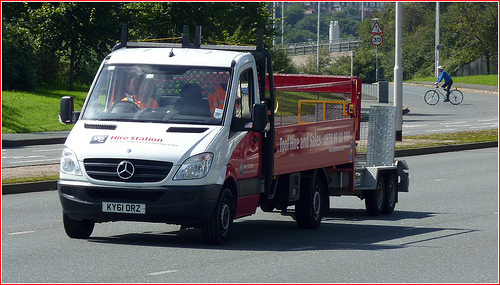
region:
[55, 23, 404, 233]
a truck riding down the street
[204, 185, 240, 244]
a tire on a truck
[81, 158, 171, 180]
a grate on the front of a train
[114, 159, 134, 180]
a silver Mercedes emblem on a truck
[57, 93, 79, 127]
a side mirror on a truck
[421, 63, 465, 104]
a person riding a bike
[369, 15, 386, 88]
a sign on the side of the road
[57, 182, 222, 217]
a black bumper on a truck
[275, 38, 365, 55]
a silver fence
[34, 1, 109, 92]
a small green tree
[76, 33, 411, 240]
truck driving on road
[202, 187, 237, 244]
tire on side of truck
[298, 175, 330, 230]
tire on side of truck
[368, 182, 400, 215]
tire on side of truck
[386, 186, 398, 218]
tire on side of truck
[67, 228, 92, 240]
tire on side of truck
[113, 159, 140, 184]
mercedes logo on front of truck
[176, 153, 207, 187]
headlight on front of truck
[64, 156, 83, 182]
headlight on front of truck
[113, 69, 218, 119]
front windshield of truck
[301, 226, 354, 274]
part of a shade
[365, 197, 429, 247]
part of a shade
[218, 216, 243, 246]
part of a wheel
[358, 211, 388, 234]
part of a shade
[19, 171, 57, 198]
edge of a road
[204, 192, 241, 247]
part of a wheel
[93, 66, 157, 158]
a man driving a truck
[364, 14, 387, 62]
a red and white road sign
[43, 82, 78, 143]
a rear view mirror on a truck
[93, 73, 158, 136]
a man wearing a orange shirt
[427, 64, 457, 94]
a person wearing a blue shirt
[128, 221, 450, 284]
white lines painted on a road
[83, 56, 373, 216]
a red and white truck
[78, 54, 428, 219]
a truck pulling a trailer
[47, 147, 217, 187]
headlights on a truck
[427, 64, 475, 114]
person riding a bike in middle of road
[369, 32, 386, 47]
30 written in a street sign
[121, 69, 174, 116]
driver of the truck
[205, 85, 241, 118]
safety jackets in the truck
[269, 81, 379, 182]
truck bed is red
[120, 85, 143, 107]
driver is wearing a seat belt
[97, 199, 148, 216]
KY6IORZ on the license plate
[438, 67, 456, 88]
biker is wearing a blue shirt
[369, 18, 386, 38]
triangle street sign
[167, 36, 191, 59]
antenna on the truck